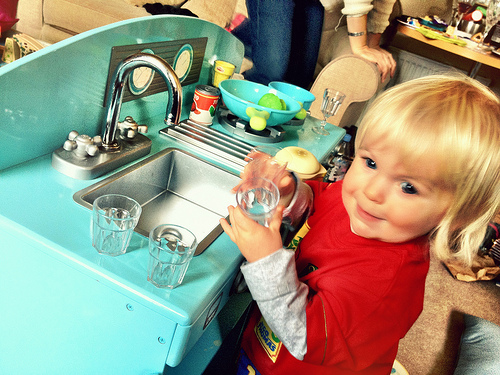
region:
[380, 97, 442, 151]
the hair is blonde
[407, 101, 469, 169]
the hair is blonde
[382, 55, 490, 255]
the hair is blonde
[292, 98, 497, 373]
this is a small boy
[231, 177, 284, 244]
he is holding a glass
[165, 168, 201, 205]
this is a sink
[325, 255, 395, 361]
the t shirt is red in color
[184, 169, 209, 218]
the sink is empty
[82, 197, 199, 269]
the glasses are two in number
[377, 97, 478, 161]
the hair is pale brown in color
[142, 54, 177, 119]
this is a tap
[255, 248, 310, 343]
the t shirt is long sleeved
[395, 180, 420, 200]
the eye is open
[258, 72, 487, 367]
a very young child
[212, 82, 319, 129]
a blue plastic bowl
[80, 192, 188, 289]
a pair of drinking glases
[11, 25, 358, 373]
a toy kitchen playset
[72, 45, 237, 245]
a fake sink on the playset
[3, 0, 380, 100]
a tan love seat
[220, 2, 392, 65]
a woman sitting on the seat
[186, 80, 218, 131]
a fake can of vegetables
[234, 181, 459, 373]
red shirt on the child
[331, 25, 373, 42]
silver bracelet on the woman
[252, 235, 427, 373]
Small Red Shirt on Child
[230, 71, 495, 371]
Young Smiling Blond Boy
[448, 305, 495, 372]
Grey Pillow on the Floor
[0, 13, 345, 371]
Blue Toy Sink Playset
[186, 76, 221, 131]
Can of Tomato Soup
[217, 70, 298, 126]
Large Blue Plastic Bowl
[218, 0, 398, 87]
Person on Tan Couch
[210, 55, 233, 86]
Tasteful Small Yellow Cup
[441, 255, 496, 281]
Brown Piece of Trash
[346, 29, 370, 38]
Fashionable Gold Bracelet on Wrist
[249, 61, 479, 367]
blonde child in red shirt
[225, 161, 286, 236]
glass in child's hands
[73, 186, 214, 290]
two glasses on blue surface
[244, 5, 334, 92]
blue jeans on legs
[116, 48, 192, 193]
curved faucet over sink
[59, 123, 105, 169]
knob on side of faucet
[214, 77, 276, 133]
blue bowl with yellow handle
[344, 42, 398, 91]
hands on arm of sofa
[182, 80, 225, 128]
can with red and white label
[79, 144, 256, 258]
steel sink in blue counter